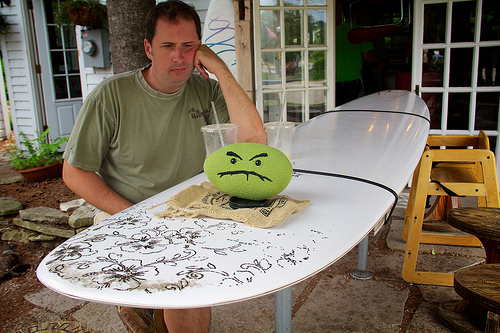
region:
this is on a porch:
[24, 6, 401, 293]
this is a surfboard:
[26, 157, 345, 317]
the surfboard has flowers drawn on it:
[33, 219, 225, 324]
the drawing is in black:
[77, 197, 252, 303]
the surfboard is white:
[65, 178, 240, 329]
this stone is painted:
[176, 136, 328, 220]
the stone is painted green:
[187, 130, 355, 275]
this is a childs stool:
[417, 138, 491, 232]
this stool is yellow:
[425, 129, 497, 264]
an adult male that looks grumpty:
[54, 1, 231, 191]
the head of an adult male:
[111, 9, 196, 91]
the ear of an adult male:
[127, 22, 151, 64]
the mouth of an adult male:
[160, 58, 194, 76]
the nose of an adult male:
[165, 43, 187, 67]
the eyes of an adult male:
[157, 38, 201, 53]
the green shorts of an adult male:
[75, 78, 220, 180]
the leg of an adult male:
[114, 296, 222, 330]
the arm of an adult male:
[50, 151, 125, 212]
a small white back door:
[18, 21, 78, 129]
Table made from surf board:
[34, 85, 437, 332]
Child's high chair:
[399, 127, 499, 289]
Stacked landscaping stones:
[2, 204, 94, 248]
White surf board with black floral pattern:
[32, 89, 433, 310]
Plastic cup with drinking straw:
[257, 95, 297, 165]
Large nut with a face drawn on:
[200, 141, 297, 203]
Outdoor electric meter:
[77, 26, 112, 72]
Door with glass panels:
[241, 3, 339, 124]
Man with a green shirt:
[61, 1, 269, 331]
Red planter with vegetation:
[3, 129, 67, 181]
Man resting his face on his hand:
[112, 3, 263, 148]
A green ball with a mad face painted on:
[200, 141, 300, 203]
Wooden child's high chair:
[396, 118, 498, 285]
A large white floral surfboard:
[33, 86, 436, 303]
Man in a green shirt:
[71, 13, 268, 229]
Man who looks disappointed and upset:
[121, 0, 265, 168]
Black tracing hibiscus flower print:
[55, 215, 259, 297]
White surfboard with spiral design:
[199, 0, 239, 92]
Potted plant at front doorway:
[10, 123, 74, 185]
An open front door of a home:
[18, 0, 103, 155]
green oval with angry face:
[196, 143, 287, 198]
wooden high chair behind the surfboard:
[426, 152, 491, 284]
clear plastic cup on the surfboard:
[192, 99, 232, 161]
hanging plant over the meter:
[52, 2, 101, 27]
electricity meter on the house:
[73, 26, 108, 70]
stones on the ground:
[16, 195, 67, 240]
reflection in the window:
[258, 4, 318, 109]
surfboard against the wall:
[201, 5, 250, 75]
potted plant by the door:
[13, 122, 63, 180]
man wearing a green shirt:
[86, 79, 232, 169]